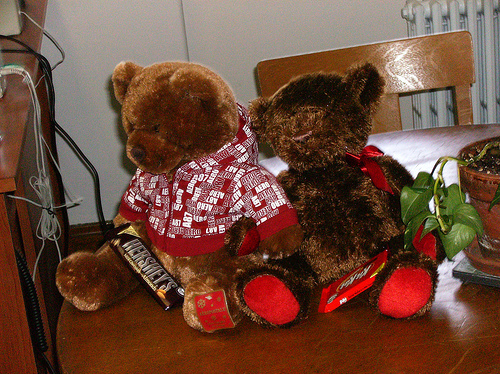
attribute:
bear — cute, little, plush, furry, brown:
[58, 62, 298, 333]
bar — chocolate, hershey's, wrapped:
[107, 224, 187, 312]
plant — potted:
[404, 137, 500, 279]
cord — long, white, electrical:
[18, 68, 70, 282]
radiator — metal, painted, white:
[399, 2, 499, 125]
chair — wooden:
[257, 29, 477, 132]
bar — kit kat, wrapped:
[320, 252, 391, 313]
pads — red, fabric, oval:
[241, 274, 304, 326]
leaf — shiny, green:
[398, 179, 433, 230]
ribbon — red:
[347, 143, 399, 195]